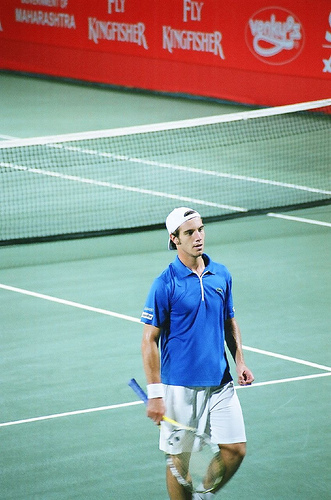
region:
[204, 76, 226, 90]
part of a red banner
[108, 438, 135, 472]
part fo a court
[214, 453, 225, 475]
edge of a racket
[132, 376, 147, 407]
part of a handle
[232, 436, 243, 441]
edge of a short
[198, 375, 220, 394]
edge of a shirt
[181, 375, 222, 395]
edge of a top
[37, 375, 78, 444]
white line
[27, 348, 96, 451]
white line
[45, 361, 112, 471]
white line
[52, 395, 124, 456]
white line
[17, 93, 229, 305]
Ground is green color.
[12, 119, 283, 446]
White lines in the ground.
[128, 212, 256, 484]
Man is walking in the ground.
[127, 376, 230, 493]
Man is holding tennis bat in hand.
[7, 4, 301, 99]
Barrier is red color.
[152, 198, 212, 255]
Man cap is white color.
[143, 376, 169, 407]
Wrist band is white color.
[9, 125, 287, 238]
Net is tied in the middle of the ground.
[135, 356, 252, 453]
Man shorts in white color.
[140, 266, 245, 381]
Man is wearing blue shirt.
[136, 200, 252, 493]
a young man standing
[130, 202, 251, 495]
a male tennis player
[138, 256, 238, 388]
a blue short sleeved shirt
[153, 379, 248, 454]
men's white shorts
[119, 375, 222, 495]
a blue and yellow tennis racket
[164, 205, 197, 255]
a white hat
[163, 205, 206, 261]
man wearing hat backwards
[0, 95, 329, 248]
a stretched tennis net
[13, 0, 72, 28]
a promotional stadium advertisement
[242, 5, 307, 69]
a promotional stadium advertisement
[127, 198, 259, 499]
The man in the blue shirt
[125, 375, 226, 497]
The racket in the man's hand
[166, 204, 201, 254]
The man's white hat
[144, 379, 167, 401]
The white wrist band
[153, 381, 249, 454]
The white shorts the man is wearing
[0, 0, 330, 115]
The red wall on the side of the court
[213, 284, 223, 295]
The alligator on the shirt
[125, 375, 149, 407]
The blue handle of the racket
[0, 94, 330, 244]
The net of the tennis court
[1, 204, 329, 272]
The shadow of the net